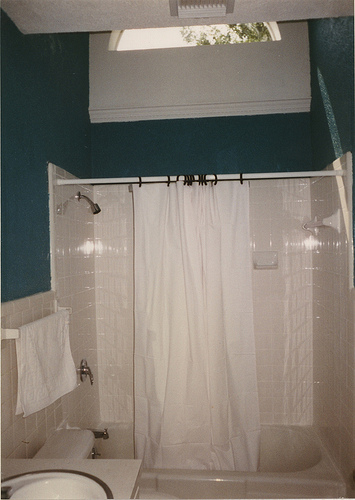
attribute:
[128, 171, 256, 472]
curtain — white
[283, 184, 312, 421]
tile — white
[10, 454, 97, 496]
bowl — sink bowl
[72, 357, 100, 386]
handle — chrome 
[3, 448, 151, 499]
counter — tan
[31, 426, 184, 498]
toilet — white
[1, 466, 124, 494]
sink — wide, shallow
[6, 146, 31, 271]
wall — blue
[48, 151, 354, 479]
tile — white